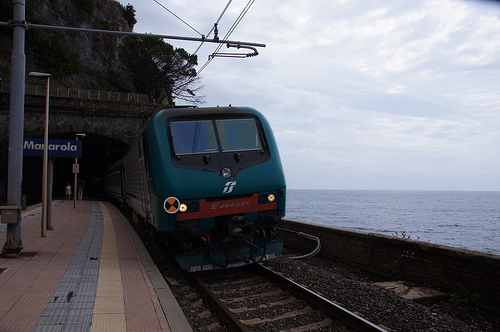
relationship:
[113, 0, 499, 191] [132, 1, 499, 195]
clouds in sky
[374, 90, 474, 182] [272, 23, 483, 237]
clouds in sky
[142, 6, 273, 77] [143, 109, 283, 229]
wires above train